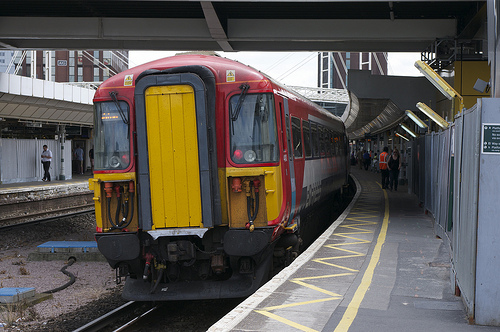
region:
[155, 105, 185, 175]
yellow door on back of train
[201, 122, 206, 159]
blue lining on door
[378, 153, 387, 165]
man wearing orange vest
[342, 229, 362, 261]
yellow swiggly lines on platform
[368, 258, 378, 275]
solid yellow line on platform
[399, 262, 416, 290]
grey pavement on platform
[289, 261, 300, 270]
solid white line on platform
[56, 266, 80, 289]
thick black hose on ground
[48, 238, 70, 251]
blue box on ground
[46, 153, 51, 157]
man wearing white shirt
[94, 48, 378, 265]
red and white train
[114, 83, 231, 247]
yellow door on train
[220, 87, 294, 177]
rectangular windows on train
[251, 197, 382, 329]
white line on platform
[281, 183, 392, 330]
yellow lines on platform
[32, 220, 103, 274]
blue bench next to train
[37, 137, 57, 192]
man walking on opposite sidewalk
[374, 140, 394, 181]
man has orange vest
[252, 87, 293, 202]
red and grey doors on side of train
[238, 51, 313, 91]
sky is grey and white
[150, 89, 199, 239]
Yellow door on train.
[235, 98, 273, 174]
Window on back of train.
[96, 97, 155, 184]
Window on back of train.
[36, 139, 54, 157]
Person has dark hair.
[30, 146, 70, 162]
Person wearing white shirt.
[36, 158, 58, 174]
Person wearing black pants.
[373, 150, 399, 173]
Person wearing orange vest.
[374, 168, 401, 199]
Person wearing dark pants.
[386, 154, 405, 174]
Person wearing black shirt.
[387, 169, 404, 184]
Person wearing dark pants.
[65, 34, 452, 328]
train on track next to platform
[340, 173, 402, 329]
yellow line on platform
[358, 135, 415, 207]
people standing on train platform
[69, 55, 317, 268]
train is red and yellow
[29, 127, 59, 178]
man walking on train platform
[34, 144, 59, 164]
man wearing white shirt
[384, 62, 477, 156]
yellow lights facing platform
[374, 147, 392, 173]
person wearing orange top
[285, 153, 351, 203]
white trim on train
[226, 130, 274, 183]
red light on train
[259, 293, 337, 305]
yellow painted line on ground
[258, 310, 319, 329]
yellow painted line on ground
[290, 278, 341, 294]
yellow painted line on ground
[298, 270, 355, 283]
yellow painted line on ground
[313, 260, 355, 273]
yellow painted line on ground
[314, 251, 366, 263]
yellow painted line on ground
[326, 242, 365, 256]
yellow painted line on ground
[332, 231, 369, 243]
yellow painted line on ground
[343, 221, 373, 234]
yellow painted line on ground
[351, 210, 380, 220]
yellow painted line on ground